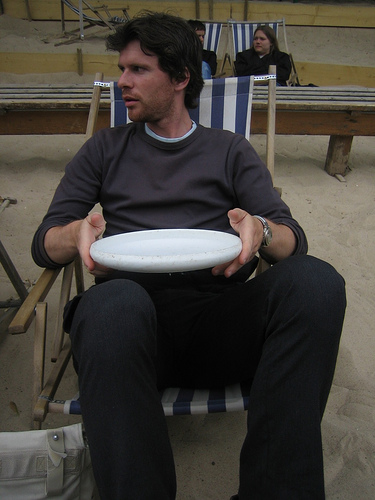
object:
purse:
[0, 425, 84, 498]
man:
[33, 10, 346, 499]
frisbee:
[91, 229, 242, 272]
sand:
[352, 359, 372, 467]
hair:
[104, 10, 193, 50]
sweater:
[32, 123, 306, 269]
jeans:
[202, 60, 210, 78]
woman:
[231, 26, 290, 84]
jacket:
[233, 48, 296, 85]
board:
[0, 87, 375, 106]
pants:
[71, 254, 348, 500]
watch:
[259, 211, 276, 249]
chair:
[9, 66, 279, 431]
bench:
[0, 86, 373, 161]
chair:
[224, 18, 300, 88]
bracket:
[88, 82, 107, 119]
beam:
[0, 111, 78, 136]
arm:
[228, 123, 308, 284]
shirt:
[141, 123, 198, 141]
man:
[186, 20, 217, 78]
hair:
[186, 18, 204, 27]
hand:
[78, 206, 108, 275]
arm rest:
[8, 264, 57, 336]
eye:
[130, 64, 147, 77]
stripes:
[222, 77, 252, 119]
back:
[212, 64, 286, 123]